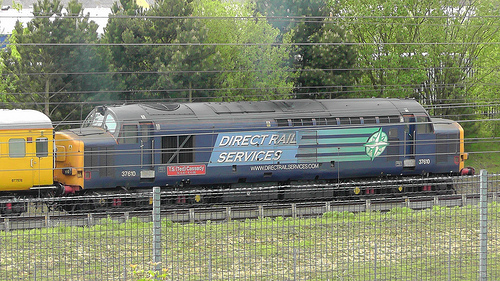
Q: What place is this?
A: It is a forest.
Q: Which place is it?
A: It is a forest.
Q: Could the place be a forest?
A: Yes, it is a forest.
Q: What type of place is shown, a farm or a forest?
A: It is a forest.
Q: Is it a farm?
A: No, it is a forest.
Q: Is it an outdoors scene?
A: Yes, it is outdoors.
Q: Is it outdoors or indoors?
A: It is outdoors.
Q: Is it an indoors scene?
A: No, it is outdoors.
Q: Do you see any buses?
A: No, there are no buses.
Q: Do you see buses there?
A: No, there are no buses.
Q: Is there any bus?
A: No, there are no buses.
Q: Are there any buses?
A: No, there are no buses.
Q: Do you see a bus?
A: No, there are no buses.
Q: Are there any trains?
A: Yes, there is a train.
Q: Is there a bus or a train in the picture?
A: Yes, there is a train.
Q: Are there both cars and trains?
A: Yes, there are both a train and a car.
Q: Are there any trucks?
A: No, there are no trucks.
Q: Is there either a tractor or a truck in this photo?
A: No, there are no trucks or tractors.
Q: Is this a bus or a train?
A: This is a train.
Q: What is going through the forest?
A: The train is going through the forest.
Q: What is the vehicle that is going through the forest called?
A: The vehicle is a train.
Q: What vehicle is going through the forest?
A: The vehicle is a train.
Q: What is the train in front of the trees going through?
A: The train is going through the forest.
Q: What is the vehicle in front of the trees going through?
A: The train is going through the forest.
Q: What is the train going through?
A: The train is going through the forest.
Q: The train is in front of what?
A: The train is in front of the trees.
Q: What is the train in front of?
A: The train is in front of the trees.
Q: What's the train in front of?
A: The train is in front of the trees.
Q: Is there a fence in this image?
A: Yes, there is a fence.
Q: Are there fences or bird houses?
A: Yes, there is a fence.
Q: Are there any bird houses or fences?
A: Yes, there is a fence.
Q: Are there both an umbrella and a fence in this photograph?
A: No, there is a fence but no umbrellas.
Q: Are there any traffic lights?
A: No, there are no traffic lights.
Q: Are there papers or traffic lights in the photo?
A: No, there are no traffic lights or papers.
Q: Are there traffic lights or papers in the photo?
A: No, there are no traffic lights or papers.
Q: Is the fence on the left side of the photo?
A: Yes, the fence is on the left of the image.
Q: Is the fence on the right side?
A: No, the fence is on the left of the image.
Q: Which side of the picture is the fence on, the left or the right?
A: The fence is on the left of the image.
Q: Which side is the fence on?
A: The fence is on the left of the image.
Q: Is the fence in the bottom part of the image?
A: Yes, the fence is in the bottom of the image.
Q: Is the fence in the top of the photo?
A: No, the fence is in the bottom of the image.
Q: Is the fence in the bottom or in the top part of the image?
A: The fence is in the bottom of the image.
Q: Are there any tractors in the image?
A: No, there are no tractors.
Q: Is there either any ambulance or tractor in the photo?
A: No, there are no tractors or ambulances.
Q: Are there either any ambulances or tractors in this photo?
A: No, there are no tractors or ambulances.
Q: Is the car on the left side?
A: Yes, the car is on the left of the image.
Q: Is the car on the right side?
A: No, the car is on the left of the image.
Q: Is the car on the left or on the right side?
A: The car is on the left of the image.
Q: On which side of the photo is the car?
A: The car is on the left of the image.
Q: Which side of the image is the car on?
A: The car is on the left of the image.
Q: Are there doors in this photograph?
A: Yes, there is a door.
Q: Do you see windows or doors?
A: Yes, there is a door.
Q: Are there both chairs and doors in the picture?
A: No, there is a door but no chairs.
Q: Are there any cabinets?
A: No, there are no cabinets.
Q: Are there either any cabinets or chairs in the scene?
A: No, there are no cabinets or chairs.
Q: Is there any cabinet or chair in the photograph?
A: No, there are no cabinets or chairs.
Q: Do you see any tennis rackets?
A: No, there are no tennis rackets.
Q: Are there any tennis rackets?
A: No, there are no tennis rackets.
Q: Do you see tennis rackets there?
A: No, there are no tennis rackets.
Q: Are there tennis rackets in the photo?
A: No, there are no tennis rackets.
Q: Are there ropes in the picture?
A: No, there are no ropes.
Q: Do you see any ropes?
A: No, there are no ropes.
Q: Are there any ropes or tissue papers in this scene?
A: No, there are no ropes or tissue papers.